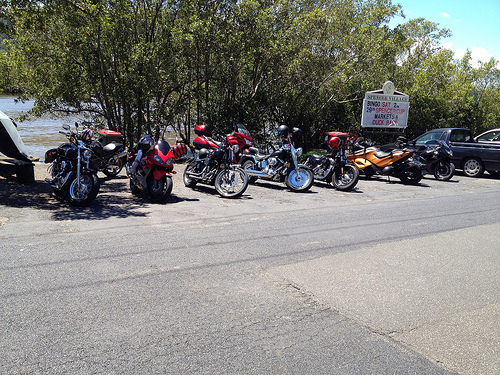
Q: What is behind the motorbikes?
A: Trees.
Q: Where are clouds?
A: In the sky.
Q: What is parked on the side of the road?
A: Motorcycles.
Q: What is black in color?
A: The street.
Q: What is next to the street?
A: Trees.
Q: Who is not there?
A: The bikers.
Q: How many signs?
A: 1.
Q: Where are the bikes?
A: On side of road.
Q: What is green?
A: Trees.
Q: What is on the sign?
A: Letters.